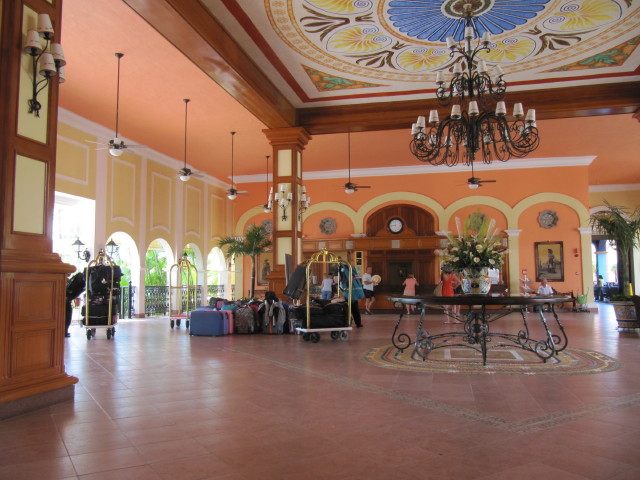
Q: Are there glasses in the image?
A: No, there are no glasses.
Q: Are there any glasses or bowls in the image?
A: No, there are no glasses or bowls.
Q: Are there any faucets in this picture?
A: No, there are no faucets.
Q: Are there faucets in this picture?
A: No, there are no faucets.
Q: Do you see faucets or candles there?
A: No, there are no faucets or candles.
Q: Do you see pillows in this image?
A: No, there are no pillows.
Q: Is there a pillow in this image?
A: No, there are no pillows.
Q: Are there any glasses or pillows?
A: No, there are no pillows or glasses.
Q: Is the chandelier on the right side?
A: Yes, the chandelier is on the right of the image.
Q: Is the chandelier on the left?
A: No, the chandelier is on the right of the image.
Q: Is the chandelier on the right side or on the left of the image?
A: The chandelier is on the right of the image.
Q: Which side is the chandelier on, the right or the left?
A: The chandelier is on the right of the image.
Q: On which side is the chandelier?
A: The chandelier is on the right of the image.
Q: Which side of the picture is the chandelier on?
A: The chandelier is on the right of the image.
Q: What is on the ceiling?
A: The chandelier is on the ceiling.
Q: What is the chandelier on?
A: The chandelier is on the ceiling.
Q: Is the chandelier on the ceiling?
A: Yes, the chandelier is on the ceiling.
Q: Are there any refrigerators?
A: No, there are no refrigerators.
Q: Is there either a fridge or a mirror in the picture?
A: No, there are no refrigerators or mirrors.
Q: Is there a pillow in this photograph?
A: No, there are no pillows.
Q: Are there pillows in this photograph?
A: No, there are no pillows.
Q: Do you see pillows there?
A: No, there are no pillows.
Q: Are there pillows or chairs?
A: No, there are no pillows or chairs.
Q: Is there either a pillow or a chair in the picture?
A: No, there are no pillows or chairs.